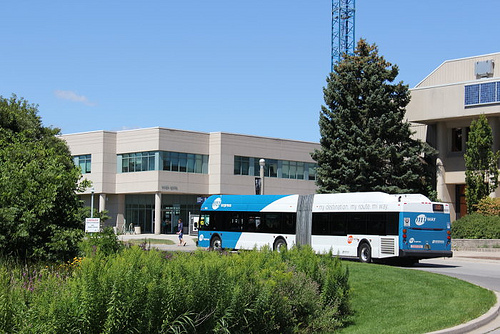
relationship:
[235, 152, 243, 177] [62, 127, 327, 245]
window on building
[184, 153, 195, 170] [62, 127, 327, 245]
window on building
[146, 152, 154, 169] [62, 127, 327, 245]
window on building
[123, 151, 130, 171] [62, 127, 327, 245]
window on building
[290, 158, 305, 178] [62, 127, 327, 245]
window on building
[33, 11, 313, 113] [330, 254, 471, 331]
sky above grass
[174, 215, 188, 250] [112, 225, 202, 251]
pedestrian walking on sidewalk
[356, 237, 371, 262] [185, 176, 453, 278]
tire of bus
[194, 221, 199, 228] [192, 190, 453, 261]
sideview mirror of bus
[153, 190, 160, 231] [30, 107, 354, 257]
support column of building